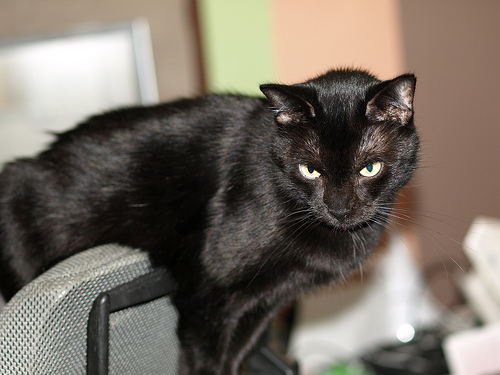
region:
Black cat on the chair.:
[1, 65, 423, 371]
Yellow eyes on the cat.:
[290, 146, 386, 182]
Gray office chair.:
[5, 230, 195, 370]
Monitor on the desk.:
[5, 21, 165, 177]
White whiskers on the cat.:
[240, 182, 465, 292]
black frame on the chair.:
[85, 265, 172, 370]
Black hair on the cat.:
[0, 65, 427, 373]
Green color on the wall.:
[193, 1, 277, 100]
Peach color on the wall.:
[273, 0, 498, 270]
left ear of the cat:
[374, 70, 421, 133]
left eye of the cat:
[354, 158, 384, 179]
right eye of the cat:
[298, 161, 327, 184]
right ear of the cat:
[258, 78, 320, 137]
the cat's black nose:
[327, 203, 357, 219]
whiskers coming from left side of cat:
[367, 196, 482, 271]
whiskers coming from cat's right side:
[225, 194, 322, 256]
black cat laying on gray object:
[0, 63, 494, 373]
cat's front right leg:
[185, 297, 232, 372]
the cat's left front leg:
[228, 311, 263, 373]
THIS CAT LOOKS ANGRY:
[1, 52, 429, 372]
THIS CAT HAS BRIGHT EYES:
[290, 137, 390, 193]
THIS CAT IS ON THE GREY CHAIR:
[0, 50, 416, 370]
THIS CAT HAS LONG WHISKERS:
[233, 176, 473, 301]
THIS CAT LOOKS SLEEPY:
[0, 53, 460, 370]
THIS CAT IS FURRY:
[0, 47, 450, 369]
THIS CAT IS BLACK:
[0, 53, 430, 371]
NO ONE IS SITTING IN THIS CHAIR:
[1, 230, 177, 371]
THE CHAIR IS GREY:
[0, 231, 186, 372]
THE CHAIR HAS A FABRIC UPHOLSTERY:
[3, 213, 193, 373]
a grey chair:
[12, 245, 162, 364]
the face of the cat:
[280, 58, 407, 218]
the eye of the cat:
[302, 164, 327, 180]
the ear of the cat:
[266, 80, 322, 127]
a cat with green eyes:
[26, 52, 443, 324]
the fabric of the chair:
[16, 276, 79, 346]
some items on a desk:
[350, 247, 490, 370]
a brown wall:
[410, 40, 497, 187]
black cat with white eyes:
[17, 57, 435, 348]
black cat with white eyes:
[0, 53, 434, 368]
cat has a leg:
[169, 262, 281, 369]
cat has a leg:
[224, 264, 335, 372]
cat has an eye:
[297, 161, 320, 180]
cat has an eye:
[361, 158, 382, 179]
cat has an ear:
[368, 71, 415, 127]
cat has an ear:
[260, 83, 322, 123]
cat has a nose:
[327, 205, 350, 219]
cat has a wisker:
[367, 202, 469, 209]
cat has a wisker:
[252, 207, 319, 225]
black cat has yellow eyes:
[295, 162, 385, 181]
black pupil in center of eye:
[366, 162, 374, 174]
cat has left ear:
[363, 70, 418, 122]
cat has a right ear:
[258, 83, 319, 122]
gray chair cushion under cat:
[1, 242, 185, 374]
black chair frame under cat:
[84, 268, 181, 374]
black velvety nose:
[326, 209, 351, 219]